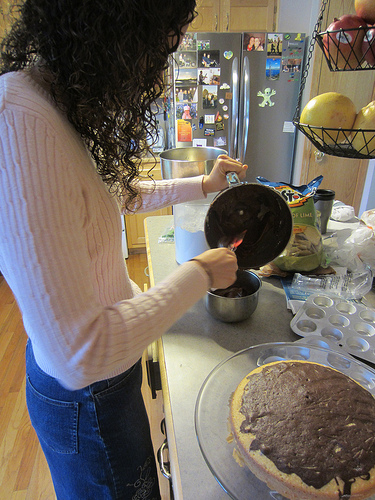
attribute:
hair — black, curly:
[0, 1, 199, 210]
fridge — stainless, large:
[147, 32, 308, 186]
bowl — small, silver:
[207, 269, 263, 321]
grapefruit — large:
[299, 91, 357, 143]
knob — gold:
[311, 145, 327, 166]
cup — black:
[312, 187, 334, 234]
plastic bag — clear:
[320, 226, 374, 281]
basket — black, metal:
[293, 122, 374, 157]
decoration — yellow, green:
[258, 84, 277, 109]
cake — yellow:
[232, 359, 374, 498]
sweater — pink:
[3, 53, 210, 392]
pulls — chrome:
[159, 442, 175, 478]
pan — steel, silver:
[287, 290, 373, 369]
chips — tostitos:
[281, 224, 322, 254]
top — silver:
[143, 209, 373, 499]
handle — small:
[143, 348, 161, 401]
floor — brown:
[2, 246, 173, 499]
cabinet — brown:
[184, 3, 279, 36]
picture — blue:
[264, 58, 281, 83]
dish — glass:
[195, 344, 373, 499]